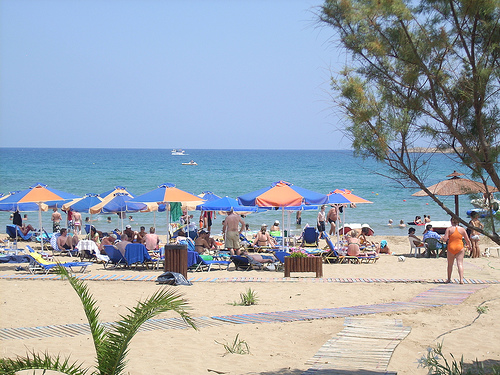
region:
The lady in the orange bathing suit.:
[442, 212, 470, 284]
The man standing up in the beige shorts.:
[218, 204, 249, 250]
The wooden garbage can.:
[157, 238, 189, 275]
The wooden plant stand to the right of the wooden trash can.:
[278, 255, 329, 273]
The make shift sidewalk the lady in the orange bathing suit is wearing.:
[201, 272, 498, 292]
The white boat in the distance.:
[167, 140, 193, 156]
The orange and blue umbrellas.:
[5, 175, 369, 230]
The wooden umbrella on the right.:
[405, 170, 494, 196]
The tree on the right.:
[314, 1, 499, 253]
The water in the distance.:
[2, 140, 492, 217]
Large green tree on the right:
[305, 1, 497, 261]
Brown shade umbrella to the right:
[408, 169, 499, 204]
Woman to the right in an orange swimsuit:
[438, 216, 468, 286]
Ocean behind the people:
[0, 142, 497, 235]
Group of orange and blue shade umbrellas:
[0, 177, 376, 215]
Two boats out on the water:
[165, 144, 200, 171]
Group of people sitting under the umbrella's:
[1, 200, 307, 260]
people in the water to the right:
[386, 209, 438, 231]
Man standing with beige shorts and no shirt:
[219, 204, 247, 261]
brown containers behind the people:
[161, 240, 327, 278]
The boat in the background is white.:
[173, 148, 189, 160]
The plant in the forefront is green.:
[59, 266, 196, 369]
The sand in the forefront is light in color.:
[263, 331, 300, 353]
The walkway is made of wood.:
[350, 330, 377, 364]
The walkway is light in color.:
[346, 328, 382, 357]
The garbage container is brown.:
[164, 243, 187, 271]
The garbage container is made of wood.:
[164, 244, 186, 268]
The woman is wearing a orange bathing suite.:
[441, 213, 463, 282]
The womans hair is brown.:
[436, 216, 469, 278]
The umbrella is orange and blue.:
[233, 181, 328, 212]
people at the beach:
[3, 167, 492, 278]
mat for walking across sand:
[248, 307, 342, 323]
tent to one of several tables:
[231, 178, 334, 215]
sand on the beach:
[274, 286, 349, 301]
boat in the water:
[171, 143, 201, 170]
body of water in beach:
[1, 152, 160, 177]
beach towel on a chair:
[122, 243, 154, 265]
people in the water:
[375, 213, 440, 225]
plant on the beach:
[0, 268, 207, 373]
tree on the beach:
[293, 0, 499, 245]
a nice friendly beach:
[10, 141, 498, 372]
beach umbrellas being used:
[17, 175, 356, 222]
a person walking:
[429, 218, 469, 288]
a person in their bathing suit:
[438, 216, 467, 278]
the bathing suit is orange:
[440, 225, 473, 257]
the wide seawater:
[11, 147, 497, 239]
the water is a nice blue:
[11, 145, 497, 242]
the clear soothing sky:
[2, 5, 492, 131]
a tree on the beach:
[306, 0, 498, 248]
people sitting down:
[37, 227, 434, 262]